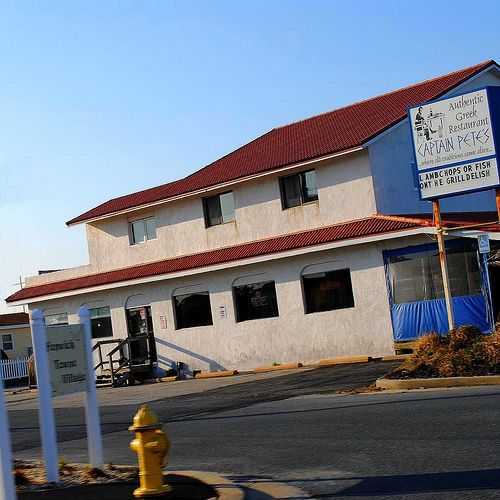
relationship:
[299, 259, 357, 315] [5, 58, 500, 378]
window on building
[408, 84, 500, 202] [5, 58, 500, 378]
sign outside of building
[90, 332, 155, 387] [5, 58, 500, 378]
staircase stands in front of building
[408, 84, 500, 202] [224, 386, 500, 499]
sign standing on road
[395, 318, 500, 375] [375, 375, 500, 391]
grass on curb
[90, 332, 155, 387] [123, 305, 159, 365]
staircase are in front of door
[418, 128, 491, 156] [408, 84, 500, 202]
captain pete's written on sign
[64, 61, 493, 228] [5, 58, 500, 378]
roof on top of building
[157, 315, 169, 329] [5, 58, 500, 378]
handicapped sign on building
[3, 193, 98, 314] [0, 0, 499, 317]
clouds are in blue sky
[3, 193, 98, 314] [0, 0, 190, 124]
white clouds are in blue sky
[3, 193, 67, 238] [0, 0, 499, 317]
clouds are in blue sky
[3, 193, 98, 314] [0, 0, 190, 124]
clouds are floating in blue sky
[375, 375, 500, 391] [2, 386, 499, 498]
curb on side of a road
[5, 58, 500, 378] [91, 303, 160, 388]
building has an entrance